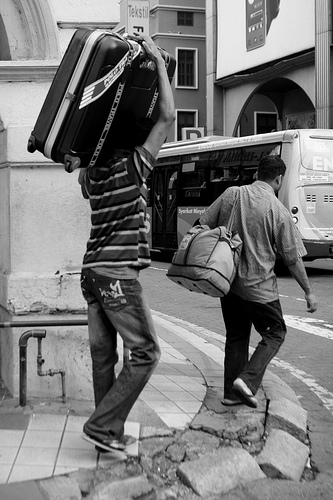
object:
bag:
[165, 190, 242, 299]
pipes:
[19, 327, 45, 407]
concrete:
[0, 303, 14, 398]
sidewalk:
[0, 303, 311, 499]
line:
[282, 310, 333, 341]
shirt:
[79, 145, 159, 274]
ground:
[0, 259, 333, 498]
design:
[96, 279, 126, 301]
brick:
[172, 397, 203, 422]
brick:
[306, 430, 332, 473]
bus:
[143, 134, 332, 263]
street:
[139, 260, 332, 499]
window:
[176, 48, 194, 91]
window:
[176, 10, 186, 26]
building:
[122, 2, 224, 149]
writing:
[97, 278, 126, 301]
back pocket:
[98, 280, 127, 312]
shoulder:
[122, 149, 139, 164]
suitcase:
[24, 18, 182, 182]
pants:
[71, 254, 160, 455]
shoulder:
[223, 184, 244, 198]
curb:
[79, 370, 310, 497]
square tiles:
[20, 426, 63, 452]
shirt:
[198, 179, 308, 305]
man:
[198, 154, 320, 410]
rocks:
[176, 444, 266, 497]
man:
[78, 26, 179, 458]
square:
[26, 411, 69, 429]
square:
[20, 429, 64, 447]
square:
[14, 446, 59, 466]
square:
[53, 448, 99, 465]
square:
[60, 430, 96, 447]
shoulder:
[78, 167, 98, 180]